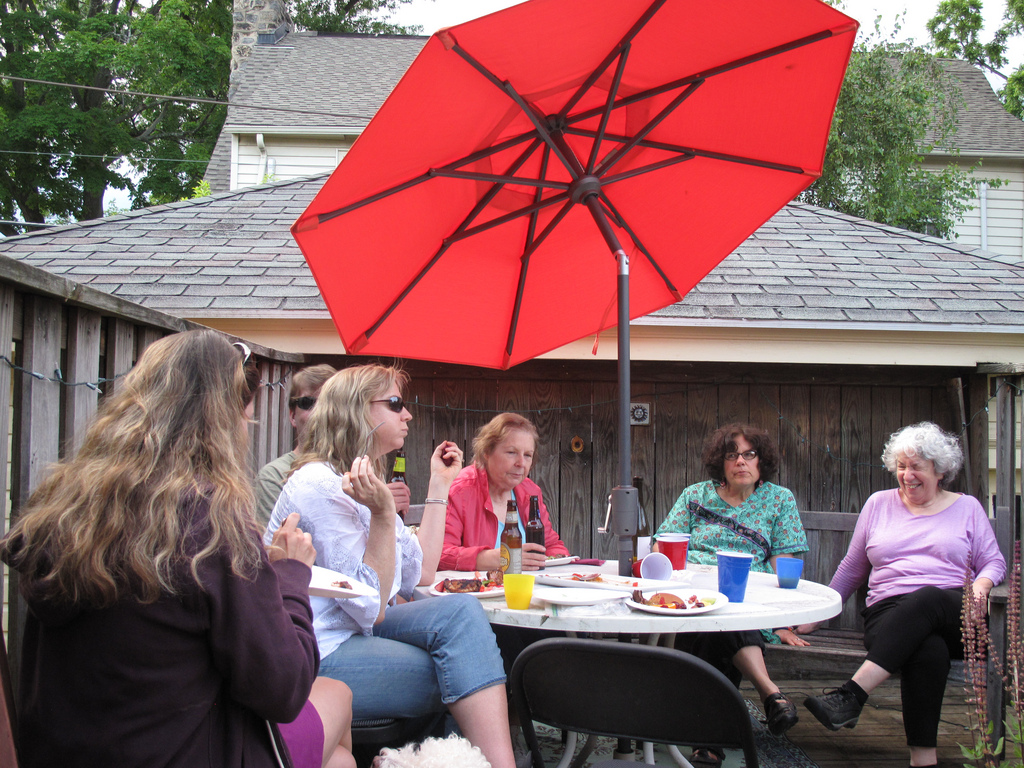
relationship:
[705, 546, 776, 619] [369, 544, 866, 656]
cup on table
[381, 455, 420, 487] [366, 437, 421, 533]
label on bottle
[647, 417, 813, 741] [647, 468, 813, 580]
woman in top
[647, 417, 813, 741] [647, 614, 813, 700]
woman wearing pants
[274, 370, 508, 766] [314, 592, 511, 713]
woman wearing pants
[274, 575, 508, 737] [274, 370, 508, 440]
pants in sunglasses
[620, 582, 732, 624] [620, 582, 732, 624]
food on plate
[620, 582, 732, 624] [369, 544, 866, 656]
plate on table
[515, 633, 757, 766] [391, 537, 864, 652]
chair pulled up to table